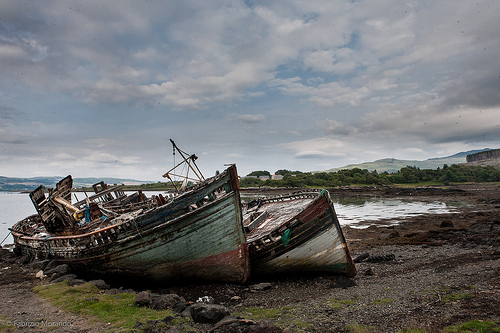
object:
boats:
[22, 160, 373, 296]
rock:
[177, 293, 238, 324]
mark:
[318, 241, 357, 266]